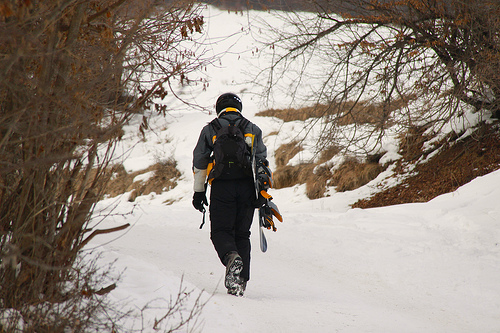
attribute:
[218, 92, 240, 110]
helmet — black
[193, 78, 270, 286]
man — walking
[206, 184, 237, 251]
pants — black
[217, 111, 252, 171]
jacket — grey, gray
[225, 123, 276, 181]
backpack — black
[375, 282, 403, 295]
snow — here, white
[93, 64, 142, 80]
bush — brown, dry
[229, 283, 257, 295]
shoes — black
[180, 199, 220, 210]
gloves — black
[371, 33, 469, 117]
trees — some, brown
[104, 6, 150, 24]
branches — small